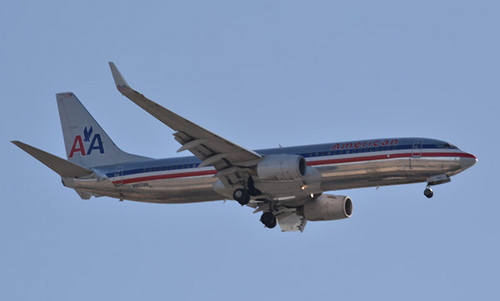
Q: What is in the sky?
A: A airplane.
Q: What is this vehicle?
A: Plane.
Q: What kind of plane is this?
A: Passenger.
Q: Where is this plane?
A: In the air.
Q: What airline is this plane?
A: American airlines.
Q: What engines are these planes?
A: Jet.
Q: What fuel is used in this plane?
A: Jet fuel.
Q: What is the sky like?
A: Clear.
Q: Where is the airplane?
A: In the sky.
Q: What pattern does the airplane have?
A: Stripes.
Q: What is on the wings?
A: The engines.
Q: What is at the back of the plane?
A: The tail.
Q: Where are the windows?
A: On the side of the plane.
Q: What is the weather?
A: Clear.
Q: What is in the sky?
A: A large plane.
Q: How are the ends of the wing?
A: Bent upward.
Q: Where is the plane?
A: In the sky.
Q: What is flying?
A: Plane.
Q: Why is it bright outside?
A: Daylight.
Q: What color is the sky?
A: Blue.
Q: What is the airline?
A: American airlines.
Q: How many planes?
A: One.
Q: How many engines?
A: Two.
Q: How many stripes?
A: Three.